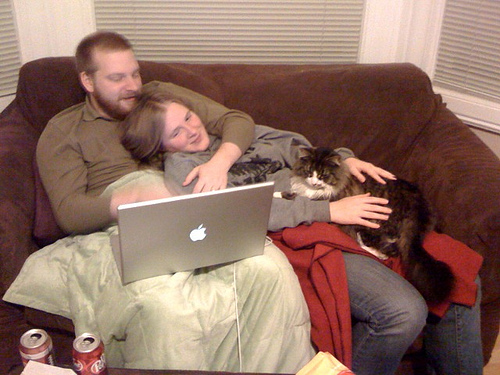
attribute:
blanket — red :
[307, 225, 352, 353]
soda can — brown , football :
[15, 320, 54, 373]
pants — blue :
[311, 233, 489, 370]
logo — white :
[185, 222, 208, 243]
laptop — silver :
[102, 176, 279, 286]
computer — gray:
[108, 180, 275, 286]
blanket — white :
[6, 167, 316, 373]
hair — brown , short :
[62, 23, 144, 109]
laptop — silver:
[86, 172, 281, 282]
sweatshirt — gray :
[163, 117, 335, 225]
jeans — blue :
[302, 195, 499, 353]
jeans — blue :
[343, 251, 481, 373]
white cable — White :
[229, 263, 259, 373]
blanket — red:
[263, 199, 493, 360]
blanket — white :
[2, 222, 321, 373]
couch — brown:
[2, 55, 496, 373]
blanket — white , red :
[265, 221, 483, 367]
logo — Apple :
[187, 218, 212, 248]